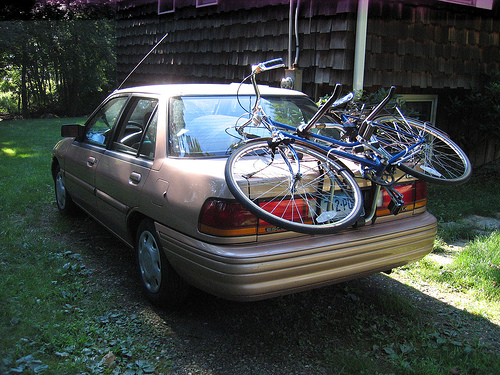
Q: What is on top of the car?
A: A bicycle.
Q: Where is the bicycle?
A: On the trunk of the car.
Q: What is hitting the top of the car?
A: Sunlight.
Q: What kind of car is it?
A: A sedan.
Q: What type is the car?
A: Four door.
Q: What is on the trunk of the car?
A: A bicycle.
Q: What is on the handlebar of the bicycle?
A: The brake.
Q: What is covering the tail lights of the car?
A: A bicycle.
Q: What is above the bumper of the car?
A: A bicycle.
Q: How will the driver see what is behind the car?
A: The window in the rear of the car.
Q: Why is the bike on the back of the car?
A: To transport the bike.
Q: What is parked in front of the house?
A: A small tan car.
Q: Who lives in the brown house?
A: The owner of the car.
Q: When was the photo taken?
A: Mid morning.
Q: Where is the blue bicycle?
A: On the back of the car.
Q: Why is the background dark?
A: Shade from a thicket of trees.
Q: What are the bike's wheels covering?
A: License plate.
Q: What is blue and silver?
A: The bike.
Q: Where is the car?
A: Outside somewhere.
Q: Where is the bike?
A: Back off car.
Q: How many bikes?
A: 1.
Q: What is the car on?
A: Ground.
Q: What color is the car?
A: Brown.